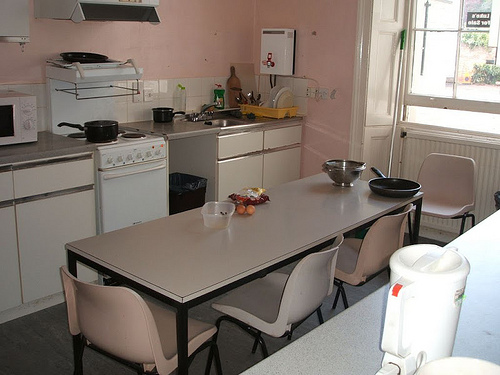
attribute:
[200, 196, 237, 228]
container — platic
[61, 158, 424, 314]
table — frying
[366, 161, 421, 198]
pan — black, frying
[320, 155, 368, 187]
bowl — silver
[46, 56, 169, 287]
range — white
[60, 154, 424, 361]
table — rectangular, beige, dining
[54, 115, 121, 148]
pot — black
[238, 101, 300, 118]
drainer — yellow, dish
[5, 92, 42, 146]
microwave — white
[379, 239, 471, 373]
pitcher — white, drink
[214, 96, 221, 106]
detergent — green, dish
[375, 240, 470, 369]
kettle — big, white, electric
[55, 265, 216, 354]
chairs — plastic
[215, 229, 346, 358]
chairs — plastic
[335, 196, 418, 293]
chairs — plastic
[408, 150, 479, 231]
chairs — plastic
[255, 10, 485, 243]
wall — pink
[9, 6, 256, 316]
wall — pink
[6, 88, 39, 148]
microwave — white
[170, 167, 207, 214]
can — black, trash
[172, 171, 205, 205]
liner — gray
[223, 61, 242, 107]
board — wooden, cutting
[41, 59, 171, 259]
stove — white, electric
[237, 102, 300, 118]
rack — plastic, yellow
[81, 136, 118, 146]
burner — stove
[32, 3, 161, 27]
vent — stove, overhead